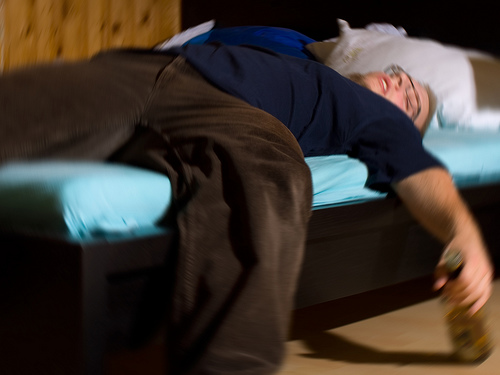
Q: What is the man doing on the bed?
A: Sleeping.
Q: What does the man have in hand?
A: Beer bottle.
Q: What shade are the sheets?
A: Blue.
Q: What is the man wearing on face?
A: Glasses.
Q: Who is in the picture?
A: A man.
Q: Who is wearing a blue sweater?
A: The man.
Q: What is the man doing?
A: Sleeping.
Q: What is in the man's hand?
A: Beer bottle.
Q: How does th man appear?
A: Passed out.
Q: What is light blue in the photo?
A: Sheets.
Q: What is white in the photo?
A: Pillow.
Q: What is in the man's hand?
A: A beer bottle.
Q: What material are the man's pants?
A: Corduroy.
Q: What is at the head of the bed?
A: A pillow.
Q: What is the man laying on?
A: A bed.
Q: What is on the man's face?
A: A pair of eyeglasses.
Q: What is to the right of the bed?
A: A paneled wall.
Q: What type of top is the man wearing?
A: A dark t-shirt.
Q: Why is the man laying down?
A: The man is intoxicated.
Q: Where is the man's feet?
A: The floor.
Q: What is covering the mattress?
A: A colorful sheet.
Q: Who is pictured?
A: A sleeping man.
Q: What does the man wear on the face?
A: Eyeglasses.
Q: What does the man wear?
A: Brownslacks and a dark shirt.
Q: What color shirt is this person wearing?
A: Blue.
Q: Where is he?
A: Bed.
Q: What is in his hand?
A: A bottle.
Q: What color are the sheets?
A: Blue.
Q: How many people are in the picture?
A: One.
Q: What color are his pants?
A: Brown.